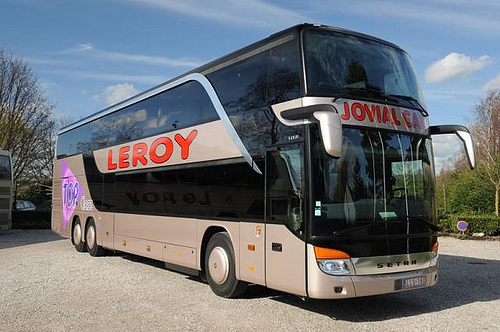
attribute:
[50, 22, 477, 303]
bus — large, tan, double decker, parked, touring, tall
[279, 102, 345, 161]
mirror — rear view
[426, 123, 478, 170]
mirror — rear view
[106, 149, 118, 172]
l — red, letter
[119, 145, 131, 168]
e — red, letter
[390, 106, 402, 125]
l — red, letter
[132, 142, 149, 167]
r — red, letter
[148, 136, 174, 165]
o — red, letter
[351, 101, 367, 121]
o — red, letter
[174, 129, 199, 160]
y — red, letter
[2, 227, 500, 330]
parking lot — gravel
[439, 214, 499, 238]
hedge — trimmed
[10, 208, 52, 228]
hedge — trimmed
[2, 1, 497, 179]
sky — blue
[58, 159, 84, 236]
decal — purple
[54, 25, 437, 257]
windows — tinted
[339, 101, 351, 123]
letter — red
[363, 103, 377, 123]
letter — red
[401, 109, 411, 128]
letter — red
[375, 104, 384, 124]
letter — red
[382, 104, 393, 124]
letter — red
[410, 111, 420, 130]
letter — red